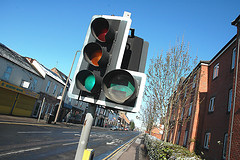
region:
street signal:
[86, 14, 108, 94]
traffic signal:
[85, 3, 139, 127]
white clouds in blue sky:
[19, 3, 36, 27]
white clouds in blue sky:
[70, 10, 83, 22]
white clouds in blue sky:
[41, 23, 67, 40]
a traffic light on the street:
[32, 6, 165, 136]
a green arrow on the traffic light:
[104, 70, 136, 100]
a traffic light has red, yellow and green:
[67, 16, 108, 92]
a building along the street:
[183, 39, 237, 155]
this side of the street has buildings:
[9, 35, 138, 137]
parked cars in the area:
[105, 118, 130, 133]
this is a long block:
[14, 109, 159, 155]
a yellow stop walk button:
[78, 134, 95, 159]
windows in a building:
[208, 54, 239, 90]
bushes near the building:
[138, 136, 172, 158]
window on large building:
[200, 128, 213, 148]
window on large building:
[218, 131, 229, 155]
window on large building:
[227, 89, 233, 113]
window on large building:
[226, 44, 238, 70]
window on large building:
[212, 59, 221, 80]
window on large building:
[206, 93, 214, 115]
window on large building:
[189, 75, 195, 92]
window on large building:
[186, 101, 192, 118]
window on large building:
[183, 128, 191, 146]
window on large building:
[2, 63, 14, 79]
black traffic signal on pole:
[73, 14, 110, 103]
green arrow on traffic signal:
[103, 68, 136, 102]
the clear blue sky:
[0, 0, 77, 45]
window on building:
[212, 61, 221, 81]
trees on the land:
[142, 57, 165, 141]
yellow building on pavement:
[0, 85, 37, 115]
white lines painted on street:
[4, 126, 79, 153]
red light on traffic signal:
[90, 14, 114, 47]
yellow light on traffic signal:
[82, 41, 106, 67]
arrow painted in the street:
[106, 138, 116, 146]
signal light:
[72, 13, 123, 102]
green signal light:
[101, 61, 145, 109]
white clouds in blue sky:
[186, 16, 211, 40]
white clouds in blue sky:
[153, 9, 158, 18]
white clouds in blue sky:
[163, 1, 191, 27]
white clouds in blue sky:
[8, 6, 24, 17]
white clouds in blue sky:
[33, 16, 56, 34]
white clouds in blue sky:
[49, 33, 74, 74]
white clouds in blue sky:
[34, 12, 67, 53]